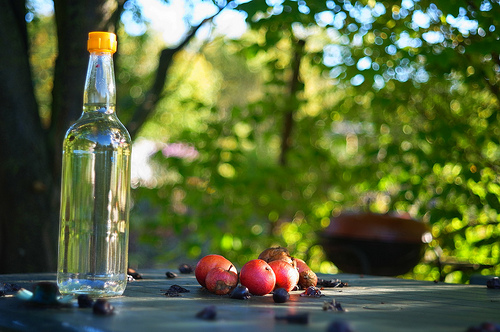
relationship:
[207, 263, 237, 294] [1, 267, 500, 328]
apple laying on table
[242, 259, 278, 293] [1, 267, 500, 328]
apple sitting on table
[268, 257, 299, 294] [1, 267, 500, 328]
apple sitting on table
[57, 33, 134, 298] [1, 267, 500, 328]
bottle sitting on table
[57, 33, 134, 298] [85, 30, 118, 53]
bottle has cap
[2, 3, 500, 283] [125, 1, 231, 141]
tree has branch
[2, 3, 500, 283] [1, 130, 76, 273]
tree has trunk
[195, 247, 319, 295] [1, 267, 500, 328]
fruit sitting on table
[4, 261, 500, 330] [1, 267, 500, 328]
berries on table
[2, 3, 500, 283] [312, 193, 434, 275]
tree by grill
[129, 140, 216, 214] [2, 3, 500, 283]
building behind tree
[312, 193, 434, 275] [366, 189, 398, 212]
grill has handle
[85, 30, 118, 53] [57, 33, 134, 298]
cap on bottle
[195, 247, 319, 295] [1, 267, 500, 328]
fruit on table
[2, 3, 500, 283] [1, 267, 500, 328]
tree behind table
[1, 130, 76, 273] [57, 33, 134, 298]
trunk behind bottle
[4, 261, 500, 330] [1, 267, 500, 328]
berries laying on table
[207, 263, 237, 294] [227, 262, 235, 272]
apple has stem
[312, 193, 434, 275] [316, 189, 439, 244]
grill has lid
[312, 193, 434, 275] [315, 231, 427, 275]
grill has bottom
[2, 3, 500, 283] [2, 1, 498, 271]
tree in background